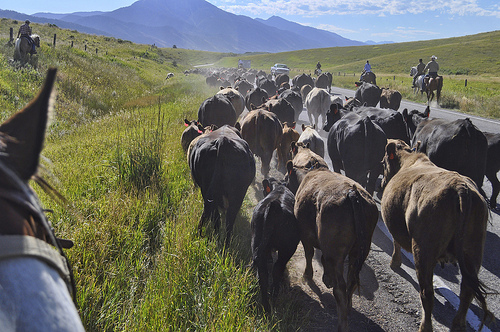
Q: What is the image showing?
A: It is showing a roadside.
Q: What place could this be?
A: It is a roadside.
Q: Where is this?
A: This is at the roadside.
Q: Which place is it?
A: It is a roadside.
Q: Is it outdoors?
A: Yes, it is outdoors.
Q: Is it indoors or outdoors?
A: It is outdoors.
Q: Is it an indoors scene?
A: No, it is outdoors.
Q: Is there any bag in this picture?
A: No, there are no bags.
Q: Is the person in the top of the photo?
A: Yes, the person is in the top of the image.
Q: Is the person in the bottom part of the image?
A: No, the person is in the top of the image.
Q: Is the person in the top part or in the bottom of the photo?
A: The person is in the top of the image.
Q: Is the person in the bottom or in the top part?
A: The person is in the top of the image.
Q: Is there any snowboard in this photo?
A: No, there are no snowboards.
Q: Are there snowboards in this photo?
A: No, there are no snowboards.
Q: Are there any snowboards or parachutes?
A: No, there are no snowboards or parachutes.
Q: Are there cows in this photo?
A: Yes, there is a cow.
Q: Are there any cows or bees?
A: Yes, there is a cow.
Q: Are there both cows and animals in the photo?
A: Yes, there are both a cow and an animal.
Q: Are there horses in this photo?
A: Yes, there is a horse.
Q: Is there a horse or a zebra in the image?
A: Yes, there is a horse.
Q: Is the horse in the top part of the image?
A: Yes, the horse is in the top of the image.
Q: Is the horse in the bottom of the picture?
A: No, the horse is in the top of the image.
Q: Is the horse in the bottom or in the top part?
A: The horse is in the top of the image.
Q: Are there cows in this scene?
A: Yes, there is a cow.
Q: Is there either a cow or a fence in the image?
A: Yes, there is a cow.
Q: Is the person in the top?
A: Yes, the person is in the top of the image.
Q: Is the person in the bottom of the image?
A: No, the person is in the top of the image.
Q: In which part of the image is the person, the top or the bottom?
A: The person is in the top of the image.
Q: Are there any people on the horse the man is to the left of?
A: Yes, there is a person on the horse.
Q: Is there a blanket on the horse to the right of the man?
A: No, there is a person on the horse.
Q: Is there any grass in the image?
A: Yes, there is grass.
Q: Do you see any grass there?
A: Yes, there is grass.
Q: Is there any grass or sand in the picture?
A: Yes, there is grass.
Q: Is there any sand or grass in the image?
A: Yes, there is grass.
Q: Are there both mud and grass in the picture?
A: No, there is grass but no mud.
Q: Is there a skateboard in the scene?
A: No, there are no skateboards.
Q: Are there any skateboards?
A: No, there are no skateboards.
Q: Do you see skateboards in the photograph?
A: No, there are no skateboards.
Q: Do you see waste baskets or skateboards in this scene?
A: No, there are no skateboards or waste baskets.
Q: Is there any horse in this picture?
A: Yes, there is a horse.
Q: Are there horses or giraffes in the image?
A: Yes, there is a horse.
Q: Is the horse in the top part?
A: Yes, the horse is in the top of the image.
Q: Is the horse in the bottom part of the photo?
A: No, the horse is in the top of the image.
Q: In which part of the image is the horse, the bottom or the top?
A: The horse is in the top of the image.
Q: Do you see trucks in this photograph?
A: No, there are no trucks.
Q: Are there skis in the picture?
A: No, there are no skis.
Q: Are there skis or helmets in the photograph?
A: No, there are no skis or helmets.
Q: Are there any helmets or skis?
A: No, there are no skis or helmets.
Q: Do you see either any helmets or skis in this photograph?
A: No, there are no skis or helmets.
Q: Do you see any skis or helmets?
A: No, there are no skis or helmets.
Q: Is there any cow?
A: Yes, there is a cow.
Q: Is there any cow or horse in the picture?
A: Yes, there is a cow.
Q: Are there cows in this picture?
A: Yes, there is a cow.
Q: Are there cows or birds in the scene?
A: Yes, there is a cow.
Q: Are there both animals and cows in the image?
A: Yes, there are both a cow and an animal.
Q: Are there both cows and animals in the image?
A: Yes, there are both a cow and an animal.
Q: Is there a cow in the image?
A: Yes, there is a cow.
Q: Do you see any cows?
A: Yes, there is a cow.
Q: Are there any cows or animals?
A: Yes, there is a cow.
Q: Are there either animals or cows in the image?
A: Yes, there is a cow.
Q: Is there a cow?
A: Yes, there is a cow.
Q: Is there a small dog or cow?
A: Yes, there is a small cow.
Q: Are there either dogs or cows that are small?
A: Yes, the cow is small.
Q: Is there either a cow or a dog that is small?
A: Yes, the cow is small.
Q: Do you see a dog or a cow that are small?
A: Yes, the cow is small.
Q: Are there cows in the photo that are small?
A: Yes, there is a small cow.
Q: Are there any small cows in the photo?
A: Yes, there is a small cow.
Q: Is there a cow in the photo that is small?
A: Yes, there is a cow that is small.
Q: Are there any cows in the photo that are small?
A: Yes, there is a cow that is small.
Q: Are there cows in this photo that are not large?
A: Yes, there is a small cow.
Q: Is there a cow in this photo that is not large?
A: Yes, there is a small cow.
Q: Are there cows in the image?
A: Yes, there is a cow.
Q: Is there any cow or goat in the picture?
A: Yes, there is a cow.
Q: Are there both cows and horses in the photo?
A: Yes, there are both a cow and a horse.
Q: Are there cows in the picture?
A: Yes, there is a cow.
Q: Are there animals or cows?
A: Yes, there is a cow.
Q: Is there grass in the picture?
A: Yes, there is grass.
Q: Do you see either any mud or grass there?
A: Yes, there is grass.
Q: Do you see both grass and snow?
A: No, there is grass but no snow.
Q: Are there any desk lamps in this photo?
A: No, there are no desk lamps.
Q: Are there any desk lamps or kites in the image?
A: No, there are no desk lamps or kites.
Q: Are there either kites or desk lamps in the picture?
A: No, there are no desk lamps or kites.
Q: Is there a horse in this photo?
A: Yes, there is a horse.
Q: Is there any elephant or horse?
A: Yes, there is a horse.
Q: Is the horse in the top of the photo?
A: Yes, the horse is in the top of the image.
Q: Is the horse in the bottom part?
A: No, the horse is in the top of the image.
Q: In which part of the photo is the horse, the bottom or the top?
A: The horse is in the top of the image.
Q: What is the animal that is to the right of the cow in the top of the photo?
A: The animal is a horse.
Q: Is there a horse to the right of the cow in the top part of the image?
A: Yes, there is a horse to the right of the cow.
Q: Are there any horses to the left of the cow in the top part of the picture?
A: No, the horse is to the right of the cow.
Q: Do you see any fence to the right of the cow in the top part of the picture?
A: No, there is a horse to the right of the cow.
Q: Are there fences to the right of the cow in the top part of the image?
A: No, there is a horse to the right of the cow.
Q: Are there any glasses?
A: No, there are no glasses.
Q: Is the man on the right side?
A: Yes, the man is on the right of the image.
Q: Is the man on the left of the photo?
A: No, the man is on the right of the image.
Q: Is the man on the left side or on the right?
A: The man is on the right of the image.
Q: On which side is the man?
A: The man is on the right of the image.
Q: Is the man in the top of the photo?
A: Yes, the man is in the top of the image.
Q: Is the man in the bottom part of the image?
A: No, the man is in the top of the image.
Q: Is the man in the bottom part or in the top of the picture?
A: The man is in the top of the image.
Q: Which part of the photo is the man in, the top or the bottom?
A: The man is in the top of the image.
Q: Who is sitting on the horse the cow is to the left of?
A: The man is sitting on the horse.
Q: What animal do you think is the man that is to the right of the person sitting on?
A: The man is sitting on the horse.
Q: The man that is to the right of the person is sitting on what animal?
A: The man is sitting on the horse.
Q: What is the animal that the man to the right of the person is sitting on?
A: The animal is a horse.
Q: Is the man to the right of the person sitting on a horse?
A: Yes, the man is sitting on a horse.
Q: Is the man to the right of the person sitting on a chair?
A: No, the man is sitting on a horse.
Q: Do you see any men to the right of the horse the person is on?
A: Yes, there is a man to the right of the horse.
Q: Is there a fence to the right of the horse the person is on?
A: No, there is a man to the right of the horse.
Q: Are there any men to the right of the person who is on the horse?
A: Yes, there is a man to the right of the person.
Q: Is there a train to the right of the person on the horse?
A: No, there is a man to the right of the person.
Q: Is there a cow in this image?
A: Yes, there is a cow.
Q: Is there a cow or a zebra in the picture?
A: Yes, there is a cow.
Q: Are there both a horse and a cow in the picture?
A: Yes, there are both a cow and a horse.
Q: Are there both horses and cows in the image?
A: Yes, there are both a cow and a horse.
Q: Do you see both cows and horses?
A: Yes, there are both a cow and a horse.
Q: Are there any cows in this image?
A: Yes, there is a cow.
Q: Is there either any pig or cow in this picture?
A: Yes, there is a cow.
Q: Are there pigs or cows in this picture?
A: Yes, there is a cow.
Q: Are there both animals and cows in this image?
A: Yes, there are both a cow and an animal.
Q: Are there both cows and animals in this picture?
A: Yes, there are both a cow and an animal.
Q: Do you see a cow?
A: Yes, there is a cow.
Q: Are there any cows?
A: Yes, there is a cow.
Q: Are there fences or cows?
A: Yes, there is a cow.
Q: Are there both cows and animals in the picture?
A: Yes, there are both a cow and an animal.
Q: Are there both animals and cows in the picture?
A: Yes, there are both a cow and an animal.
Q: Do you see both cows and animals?
A: Yes, there are both a cow and an animal.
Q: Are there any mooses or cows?
A: Yes, there is a cow.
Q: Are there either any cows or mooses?
A: Yes, there is a cow.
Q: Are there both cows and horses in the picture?
A: Yes, there are both a cow and a horse.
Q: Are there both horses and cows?
A: Yes, there are both a cow and a horse.